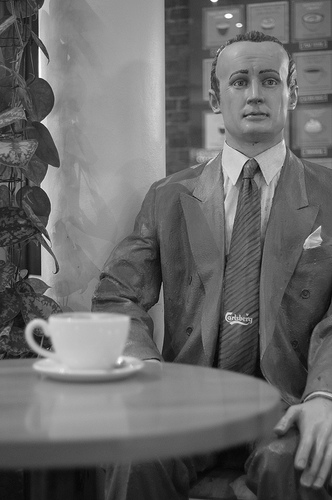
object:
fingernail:
[295, 457, 304, 467]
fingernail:
[300, 475, 312, 484]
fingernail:
[315, 478, 323, 487]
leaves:
[1, 0, 61, 361]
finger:
[293, 431, 317, 472]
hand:
[273, 394, 332, 490]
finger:
[298, 436, 327, 490]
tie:
[219, 157, 262, 375]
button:
[185, 273, 192, 283]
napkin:
[300, 220, 325, 257]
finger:
[272, 403, 299, 436]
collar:
[218, 138, 286, 186]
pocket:
[298, 238, 332, 269]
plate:
[31, 352, 142, 385]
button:
[297, 286, 311, 301]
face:
[219, 43, 291, 137]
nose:
[245, 81, 267, 103]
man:
[91, 30, 332, 409]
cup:
[23, 308, 130, 373]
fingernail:
[272, 423, 281, 433]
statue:
[91, 30, 332, 500]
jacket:
[91, 147, 332, 404]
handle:
[24, 319, 56, 359]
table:
[0, 356, 286, 471]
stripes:
[233, 257, 249, 310]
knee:
[246, 418, 321, 499]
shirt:
[219, 138, 288, 257]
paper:
[302, 225, 323, 250]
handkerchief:
[302, 225, 326, 252]